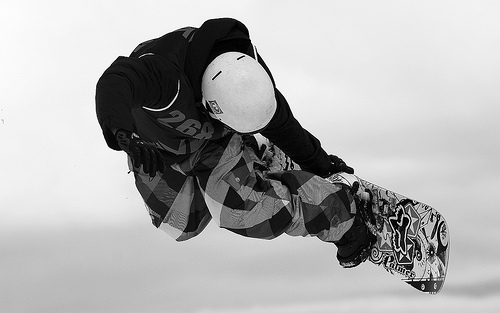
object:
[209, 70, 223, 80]
space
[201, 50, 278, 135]
helmet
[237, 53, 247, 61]
space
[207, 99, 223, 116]
sticker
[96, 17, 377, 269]
person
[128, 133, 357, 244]
pants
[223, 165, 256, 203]
pocket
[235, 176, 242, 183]
button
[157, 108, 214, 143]
number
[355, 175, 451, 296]
board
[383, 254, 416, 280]
word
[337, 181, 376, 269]
boot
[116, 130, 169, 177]
glove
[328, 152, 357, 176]
glove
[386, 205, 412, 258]
logo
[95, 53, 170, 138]
arm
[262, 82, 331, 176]
arm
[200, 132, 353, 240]
leg